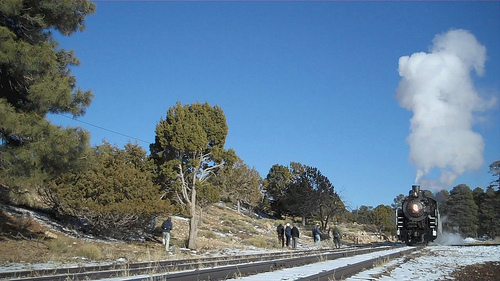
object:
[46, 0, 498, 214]
sky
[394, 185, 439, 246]
train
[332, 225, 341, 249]
people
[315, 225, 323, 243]
people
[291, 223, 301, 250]
people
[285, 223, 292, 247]
people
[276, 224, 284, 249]
people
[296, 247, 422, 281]
tracks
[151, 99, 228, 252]
tree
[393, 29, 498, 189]
smoke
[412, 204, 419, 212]
spot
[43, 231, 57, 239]
stone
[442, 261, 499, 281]
grass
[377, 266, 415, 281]
snow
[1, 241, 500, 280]
ground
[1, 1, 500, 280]
photo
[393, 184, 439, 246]
front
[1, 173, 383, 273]
hill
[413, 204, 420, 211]
headlight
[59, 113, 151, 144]
line